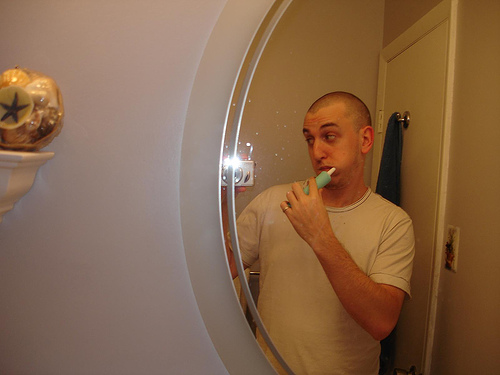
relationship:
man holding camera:
[245, 87, 425, 374] [220, 153, 257, 190]